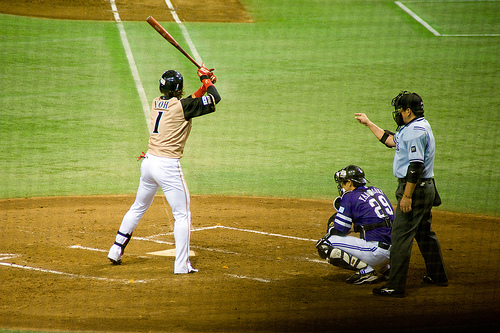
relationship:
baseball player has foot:
[106, 62, 221, 274] [172, 262, 200, 273]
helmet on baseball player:
[159, 68, 184, 91] [106, 62, 221, 274]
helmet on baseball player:
[333, 164, 371, 196] [315, 164, 396, 284]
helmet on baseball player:
[331, 162, 373, 187] [315, 164, 396, 284]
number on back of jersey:
[152, 111, 164, 134] [144, 89, 213, 153]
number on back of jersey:
[152, 111, 164, 134] [140, 76, 221, 158]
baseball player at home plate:
[106, 62, 221, 274] [146, 248, 199, 258]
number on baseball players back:
[149, 110, 168, 135] [137, 97, 194, 153]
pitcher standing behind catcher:
[354, 90, 450, 297] [318, 163, 403, 283]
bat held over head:
[129, 12, 245, 85] [389, 88, 425, 122]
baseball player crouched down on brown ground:
[315, 164, 396, 284] [271, 241, 323, 283]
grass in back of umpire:
[284, 30, 346, 73] [356, 42, 473, 310]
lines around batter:
[2, 223, 332, 284] [108, 64, 220, 271]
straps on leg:
[113, 230, 130, 245] [107, 150, 157, 263]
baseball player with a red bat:
[106, 62, 221, 274] [144, 13, 217, 77]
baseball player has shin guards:
[315, 164, 396, 284] [318, 226, 363, 267]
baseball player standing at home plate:
[104, 13, 221, 275] [143, 244, 198, 261]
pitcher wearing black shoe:
[354, 90, 450, 297] [420, 269, 445, 285]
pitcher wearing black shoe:
[354, 90, 450, 297] [373, 282, 408, 297]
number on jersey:
[365, 191, 395, 219] [148, 93, 217, 159]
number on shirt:
[149, 110, 168, 135] [391, 118, 437, 182]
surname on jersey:
[355, 185, 385, 202] [334, 185, 395, 245]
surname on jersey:
[150, 98, 171, 109] [148, 93, 217, 159]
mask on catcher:
[330, 174, 355, 193] [316, 165, 396, 285]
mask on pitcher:
[390, 88, 409, 124] [354, 90, 450, 297]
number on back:
[369, 195, 394, 219] [144, 95, 194, 162]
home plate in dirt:
[152, 212, 227, 289] [8, 190, 484, 320]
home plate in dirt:
[152, 212, 227, 289] [3, 1, 243, 22]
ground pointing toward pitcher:
[439, 86, 491, 143] [346, 83, 451, 302]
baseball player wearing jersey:
[315, 164, 396, 284] [332, 187, 393, 238]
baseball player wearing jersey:
[315, 164, 396, 284] [144, 93, 215, 151]